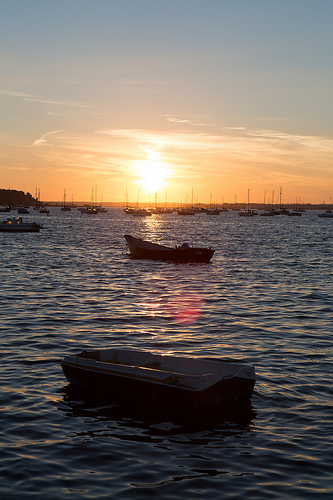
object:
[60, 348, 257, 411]
boat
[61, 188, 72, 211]
sailboat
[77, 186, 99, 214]
sailboat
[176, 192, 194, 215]
sailboat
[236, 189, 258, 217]
sailboat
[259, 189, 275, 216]
sailboat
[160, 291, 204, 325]
lens flare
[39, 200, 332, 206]
horizon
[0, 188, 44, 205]
hill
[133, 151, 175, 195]
sun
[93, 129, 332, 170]
cloud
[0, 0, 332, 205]
sky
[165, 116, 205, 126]
cloud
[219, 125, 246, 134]
cloud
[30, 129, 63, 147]
cloud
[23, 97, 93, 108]
cloud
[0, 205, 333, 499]
water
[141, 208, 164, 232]
sun reflection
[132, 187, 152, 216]
sailboat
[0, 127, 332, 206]
sunset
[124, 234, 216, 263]
boat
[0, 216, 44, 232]
boat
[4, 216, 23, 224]
cabin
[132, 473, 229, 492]
ripple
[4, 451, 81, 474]
ripple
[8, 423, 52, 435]
ripple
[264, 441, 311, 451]
ripple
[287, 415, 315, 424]
ripple